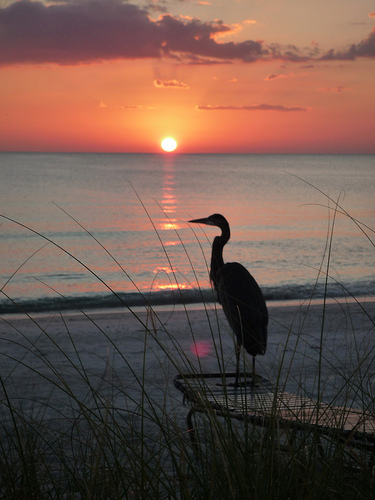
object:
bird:
[187, 214, 268, 387]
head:
[187, 213, 229, 226]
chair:
[172, 373, 375, 459]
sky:
[0, 0, 375, 153]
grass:
[0, 170, 375, 499]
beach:
[0, 300, 375, 499]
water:
[0, 151, 374, 297]